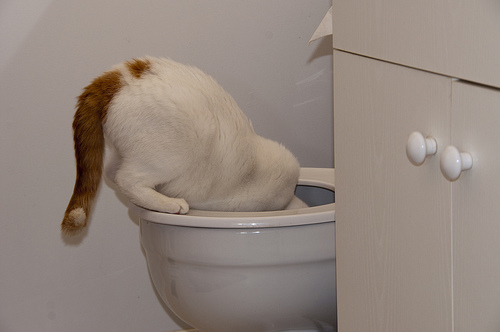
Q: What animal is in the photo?
A: A cat.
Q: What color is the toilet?
A: White.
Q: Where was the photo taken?
A: A bathroom.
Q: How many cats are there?
A: One.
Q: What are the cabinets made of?
A: Wood.